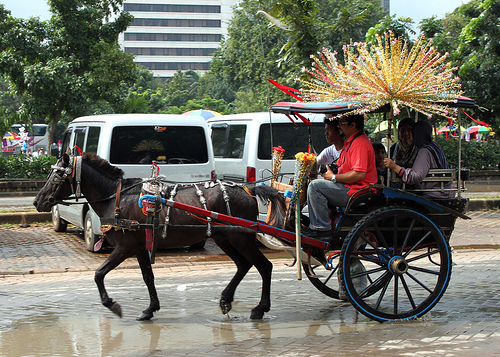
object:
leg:
[212, 234, 254, 314]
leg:
[90, 245, 130, 318]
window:
[111, 123, 211, 170]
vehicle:
[205, 111, 325, 250]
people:
[295, 110, 455, 239]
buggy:
[270, 58, 477, 324]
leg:
[235, 233, 273, 320]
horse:
[32, 144, 287, 322]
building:
[95, 0, 242, 85]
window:
[122, 4, 225, 78]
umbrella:
[436, 125, 493, 140]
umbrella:
[0, 128, 24, 138]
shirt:
[334, 130, 378, 197]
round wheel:
[335, 203, 452, 322]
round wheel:
[301, 242, 393, 301]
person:
[388, 117, 417, 194]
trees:
[175, 60, 226, 112]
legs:
[92, 231, 272, 322]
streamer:
[264, 75, 304, 102]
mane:
[83, 147, 127, 182]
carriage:
[32, 29, 477, 323]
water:
[0, 263, 497, 357]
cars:
[50, 112, 215, 252]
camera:
[318, 164, 338, 175]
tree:
[447, 1, 497, 131]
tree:
[209, 0, 404, 116]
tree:
[0, 0, 135, 125]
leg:
[135, 231, 162, 321]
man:
[305, 111, 375, 240]